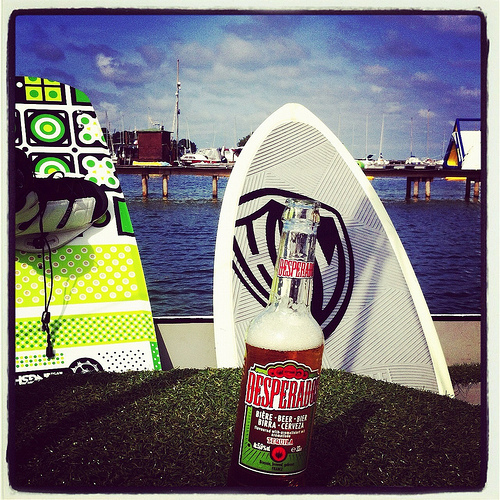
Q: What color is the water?
A: Blue and gray.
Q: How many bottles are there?
A: One.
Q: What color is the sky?
A: Blue.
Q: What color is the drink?
A: Red.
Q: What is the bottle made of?
A: Glass.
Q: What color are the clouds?
A: White.